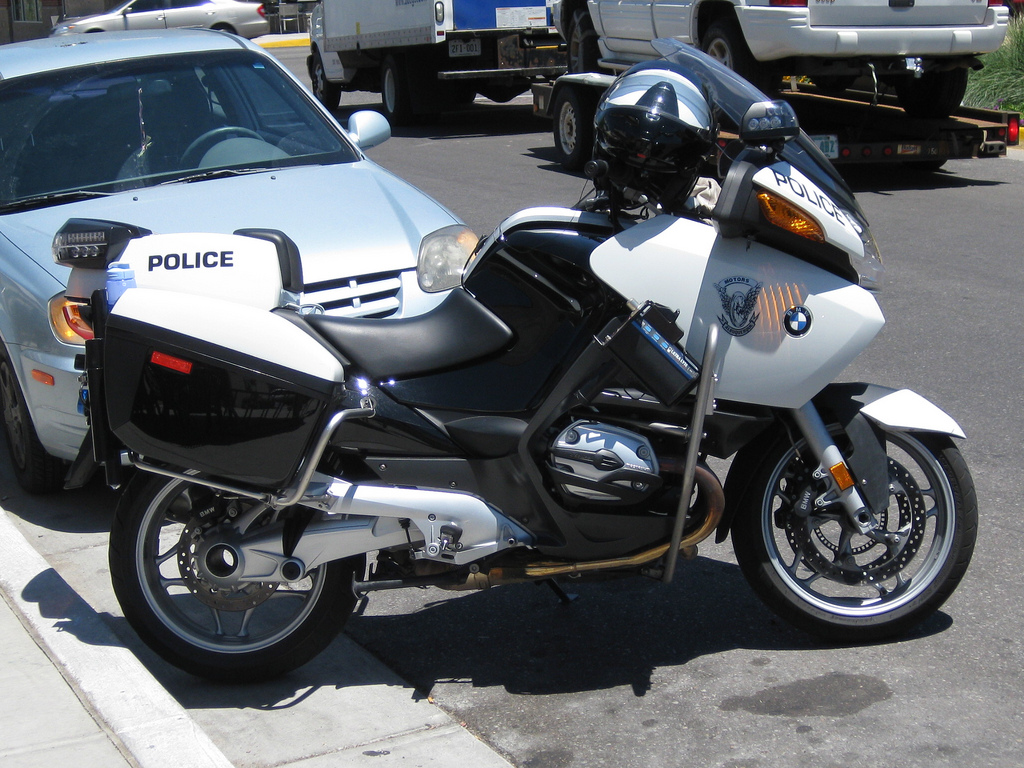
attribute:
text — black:
[141, 248, 247, 277]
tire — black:
[92, 453, 371, 709]